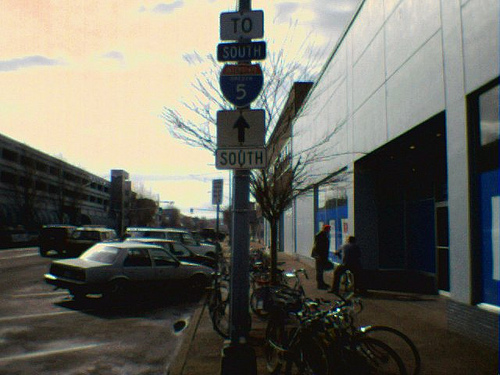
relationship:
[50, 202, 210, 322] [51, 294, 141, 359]
car parked on street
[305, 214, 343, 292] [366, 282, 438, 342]
person on sidewalk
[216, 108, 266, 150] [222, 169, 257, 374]
sign on pole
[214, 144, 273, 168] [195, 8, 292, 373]
sign on pole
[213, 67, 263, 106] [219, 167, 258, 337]
sign on pole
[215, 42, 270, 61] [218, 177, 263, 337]
sign on pole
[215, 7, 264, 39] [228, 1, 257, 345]
sign on pole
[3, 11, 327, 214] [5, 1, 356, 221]
cloud in sky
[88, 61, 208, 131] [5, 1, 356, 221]
clouds in sky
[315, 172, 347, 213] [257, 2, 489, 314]
window on building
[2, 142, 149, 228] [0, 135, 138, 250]
windows on building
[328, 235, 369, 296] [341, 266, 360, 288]
man sitting on bike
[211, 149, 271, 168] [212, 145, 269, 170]
south on sign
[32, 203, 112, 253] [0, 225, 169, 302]
vehicles on road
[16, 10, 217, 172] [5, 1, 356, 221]
white clouds in sky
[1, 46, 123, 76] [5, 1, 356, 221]
clouds in sky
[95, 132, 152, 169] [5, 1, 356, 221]
clouds in sky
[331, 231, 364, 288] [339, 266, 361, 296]
man sitting on bike